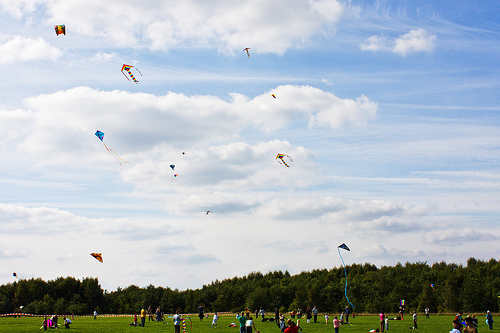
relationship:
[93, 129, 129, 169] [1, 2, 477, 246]
kite in sky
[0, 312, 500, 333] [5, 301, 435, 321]
grass in background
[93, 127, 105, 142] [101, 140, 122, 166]
kite with a tail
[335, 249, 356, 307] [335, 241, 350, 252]
tail on kite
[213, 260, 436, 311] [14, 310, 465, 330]
trees behind field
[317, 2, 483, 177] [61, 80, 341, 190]
sky streaked with clouds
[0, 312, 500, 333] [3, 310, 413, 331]
grass of field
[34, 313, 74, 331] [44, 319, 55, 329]
people putting together a kite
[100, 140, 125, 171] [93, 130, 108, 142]
tail of kite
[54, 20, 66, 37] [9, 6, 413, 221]
kite in air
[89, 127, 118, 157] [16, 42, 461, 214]
kite in mid air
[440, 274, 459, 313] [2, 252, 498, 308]
trees has leaves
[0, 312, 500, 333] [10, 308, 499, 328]
grass on field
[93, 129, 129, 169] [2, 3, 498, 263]
kite on sky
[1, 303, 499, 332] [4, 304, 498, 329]
crowd in park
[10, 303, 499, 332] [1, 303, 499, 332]
people in crowd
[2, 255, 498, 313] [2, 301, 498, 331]
trees in park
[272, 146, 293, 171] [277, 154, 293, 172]
kite has tail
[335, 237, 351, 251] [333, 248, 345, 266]
kite has tail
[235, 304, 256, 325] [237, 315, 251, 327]
person has top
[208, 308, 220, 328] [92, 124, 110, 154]
person has kite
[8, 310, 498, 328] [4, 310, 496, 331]
grass on ground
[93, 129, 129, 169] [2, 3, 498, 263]
kite in sky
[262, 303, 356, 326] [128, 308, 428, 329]
people on grass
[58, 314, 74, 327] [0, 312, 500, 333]
people crouching in grass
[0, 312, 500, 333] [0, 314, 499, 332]
grass on field